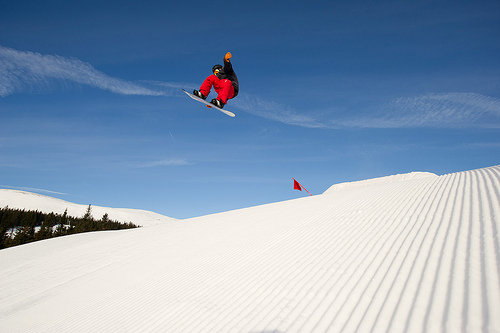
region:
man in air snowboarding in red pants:
[182, 48, 254, 124]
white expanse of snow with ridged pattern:
[0, 152, 499, 326]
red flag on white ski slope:
[290, 174, 316, 199]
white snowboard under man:
[183, 84, 233, 121]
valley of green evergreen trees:
[1, 201, 138, 248]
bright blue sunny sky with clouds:
[1, 10, 494, 218]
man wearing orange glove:
[191, 48, 251, 124]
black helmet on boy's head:
[181, 49, 243, 106]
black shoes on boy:
[186, 87, 227, 105]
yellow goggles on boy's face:
[211, 68, 221, 76]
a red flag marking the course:
[279, 170, 316, 202]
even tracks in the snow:
[383, 168, 488, 330]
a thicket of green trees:
[0, 200, 109, 237]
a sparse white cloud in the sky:
[4, 45, 164, 108]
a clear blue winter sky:
[16, 8, 460, 68]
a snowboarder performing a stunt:
[180, 32, 256, 124]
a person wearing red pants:
[157, 40, 255, 120]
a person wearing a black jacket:
[160, 35, 250, 117]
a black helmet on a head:
[212, 62, 222, 69]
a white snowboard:
[181, 89, 237, 121]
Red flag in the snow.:
[286, 173, 316, 198]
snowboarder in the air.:
[180, 48, 242, 119]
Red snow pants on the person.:
[181, 50, 246, 122]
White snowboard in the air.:
[178, 85, 237, 122]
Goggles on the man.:
[208, 60, 223, 77]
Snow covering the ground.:
[0, 165, 497, 331]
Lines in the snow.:
[28, 163, 495, 330]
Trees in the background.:
[1, 201, 141, 255]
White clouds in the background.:
[0, 39, 497, 135]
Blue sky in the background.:
[1, 0, 496, 224]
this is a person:
[182, 43, 263, 141]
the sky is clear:
[297, 47, 369, 101]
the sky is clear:
[144, 158, 231, 216]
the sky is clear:
[356, 78, 381, 109]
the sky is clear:
[257, 13, 324, 63]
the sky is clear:
[367, 40, 399, 75]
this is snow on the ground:
[213, 234, 285, 293]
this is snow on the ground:
[336, 180, 403, 270]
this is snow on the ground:
[172, 220, 252, 292]